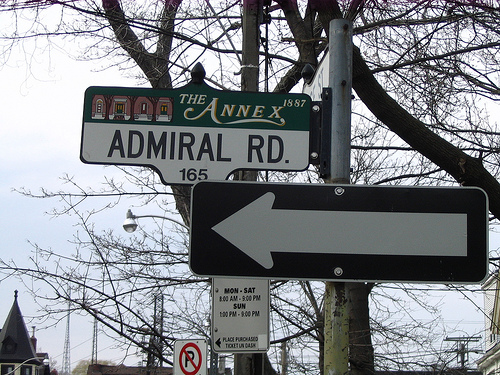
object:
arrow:
[211, 191, 467, 269]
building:
[0, 289, 52, 374]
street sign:
[79, 84, 313, 186]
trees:
[258, 0, 331, 93]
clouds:
[0, 0, 92, 186]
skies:
[0, 108, 79, 178]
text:
[106, 92, 307, 181]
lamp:
[122, 208, 138, 234]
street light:
[124, 210, 226, 373]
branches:
[0, 0, 499, 370]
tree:
[0, 0, 190, 88]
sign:
[210, 274, 271, 355]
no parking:
[171, 339, 208, 374]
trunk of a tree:
[356, 48, 499, 187]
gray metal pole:
[326, 17, 353, 185]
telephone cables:
[57, 271, 173, 357]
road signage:
[77, 84, 312, 186]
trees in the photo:
[352, 1, 499, 230]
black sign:
[185, 178, 491, 283]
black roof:
[0, 289, 37, 354]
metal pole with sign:
[239, 11, 261, 90]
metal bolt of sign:
[309, 105, 320, 163]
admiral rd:
[104, 128, 288, 183]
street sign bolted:
[334, 186, 345, 276]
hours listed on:
[218, 286, 261, 318]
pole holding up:
[312, 173, 381, 371]